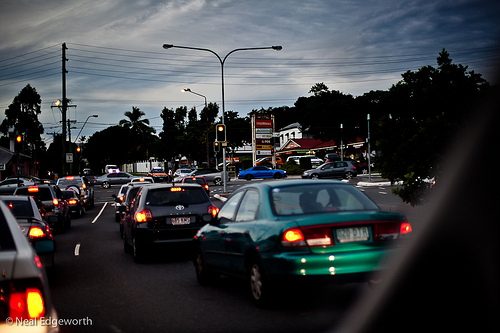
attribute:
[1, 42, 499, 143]
wires — several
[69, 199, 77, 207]
taillight — rear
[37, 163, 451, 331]
street — busy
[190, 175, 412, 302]
car — green, nearby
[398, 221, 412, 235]
lights — on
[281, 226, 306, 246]
lights — on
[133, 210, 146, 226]
lights — on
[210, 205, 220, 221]
lights — on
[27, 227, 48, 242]
lights — on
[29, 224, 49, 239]
tail light — bright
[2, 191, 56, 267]
car — dark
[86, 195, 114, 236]
white line — white 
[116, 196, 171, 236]
taillight — rear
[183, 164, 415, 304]
car — green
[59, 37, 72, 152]
pole — tall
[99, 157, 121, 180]
suv — white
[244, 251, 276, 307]
tire — black, round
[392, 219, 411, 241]
taillight — rear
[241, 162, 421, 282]
car — grreen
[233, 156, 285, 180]
car — Blue 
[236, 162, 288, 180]
car — blue 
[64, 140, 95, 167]
light — red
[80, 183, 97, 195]
tail light — red 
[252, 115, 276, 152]
signs — business sign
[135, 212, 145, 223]
taillight — back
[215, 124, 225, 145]
street light — nearby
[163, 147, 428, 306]
cars — parked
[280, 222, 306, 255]
taillight — red 